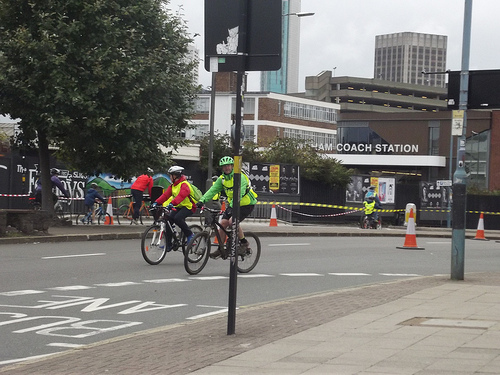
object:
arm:
[198, 176, 223, 201]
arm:
[153, 182, 173, 204]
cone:
[395, 204, 424, 252]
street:
[0, 235, 499, 367]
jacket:
[153, 177, 197, 215]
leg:
[215, 208, 233, 250]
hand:
[164, 202, 176, 212]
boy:
[146, 166, 203, 251]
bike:
[139, 206, 207, 266]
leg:
[132, 190, 142, 218]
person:
[129, 166, 156, 221]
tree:
[0, 0, 204, 227]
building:
[373, 31, 447, 89]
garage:
[303, 71, 447, 113]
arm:
[169, 183, 189, 206]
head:
[217, 155, 236, 175]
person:
[195, 154, 259, 260]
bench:
[0, 196, 52, 210]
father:
[360, 196, 383, 230]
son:
[360, 185, 383, 206]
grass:
[0, 214, 50, 239]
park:
[0, 0, 212, 217]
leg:
[227, 209, 254, 240]